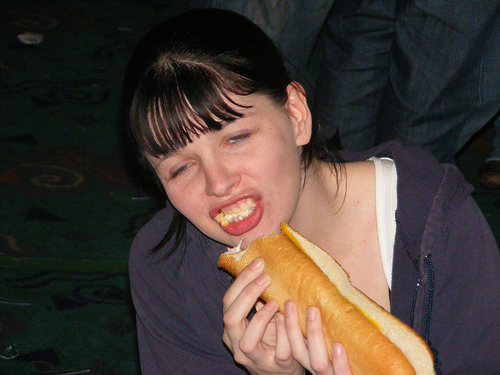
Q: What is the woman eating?
A: Bread.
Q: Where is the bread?
A: In the woman's hands.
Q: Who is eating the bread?
A: The woman.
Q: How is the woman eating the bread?
A: With her hands.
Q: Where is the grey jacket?
A: On the woman.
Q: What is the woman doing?
A: Eating bread.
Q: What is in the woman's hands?
A: A sandwich.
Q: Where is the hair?
A: On the woman's head.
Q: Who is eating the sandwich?
A: The woman.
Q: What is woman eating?
A: Sandwich.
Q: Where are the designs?
A: On carpet.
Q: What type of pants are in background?
A: Blue jeans.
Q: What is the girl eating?
A: Huge hotdog.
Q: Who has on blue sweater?
A: The girl.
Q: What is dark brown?
A: Girl's hair.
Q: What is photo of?
A: Girl eating hotdog.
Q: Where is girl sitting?
A: On carpet.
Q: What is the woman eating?
A: A sandwich.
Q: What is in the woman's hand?
A: A large sandwich.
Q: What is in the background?
A: A pair of legs.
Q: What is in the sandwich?
A: Meat.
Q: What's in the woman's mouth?
A: Sandwich.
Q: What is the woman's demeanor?
A: Relaxed.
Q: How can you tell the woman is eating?
A: There is food In the mouth.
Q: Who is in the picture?
A: A woman.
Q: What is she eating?
A: A long sandwich.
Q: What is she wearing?
A: A hoodie.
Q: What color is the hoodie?
A: Dark purple.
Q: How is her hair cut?
A: In bangs.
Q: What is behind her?
A: Legs.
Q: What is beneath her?
A: A rug.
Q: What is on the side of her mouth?
A: Food.